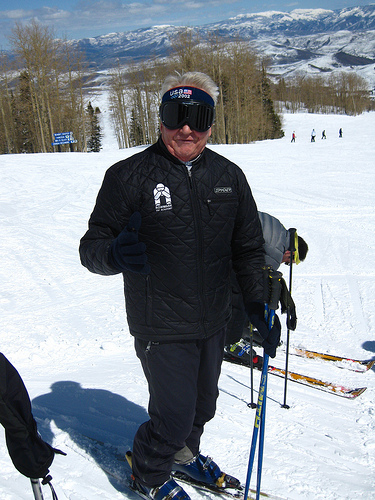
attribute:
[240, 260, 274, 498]
ski poles — blue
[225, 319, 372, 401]
skis — yellow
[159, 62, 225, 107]
hair — white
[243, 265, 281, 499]
poles — blue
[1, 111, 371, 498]
ground snow — white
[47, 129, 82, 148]
sign — blue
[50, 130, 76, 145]
sign — blue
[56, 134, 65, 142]
lettering — white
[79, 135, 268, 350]
jacket — black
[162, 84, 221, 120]
headband — usa, 2005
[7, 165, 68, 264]
snow — white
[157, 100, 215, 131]
goggles — ski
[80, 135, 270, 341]
coat — black